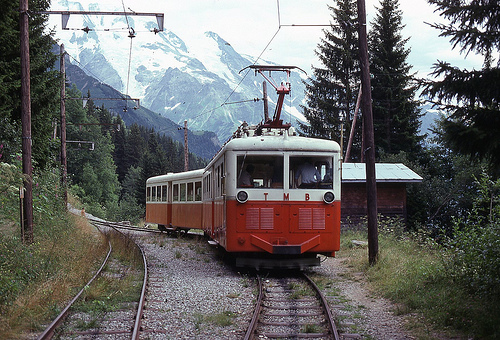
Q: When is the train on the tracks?
A: Daytime.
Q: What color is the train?
A: Red and white.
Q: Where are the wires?
A: Over the tracks.